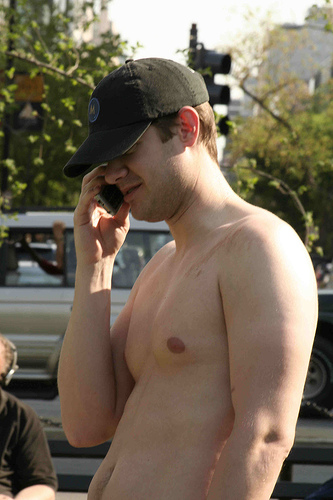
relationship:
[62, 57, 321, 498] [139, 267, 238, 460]
man has torso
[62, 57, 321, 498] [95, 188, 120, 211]
man holding cell phone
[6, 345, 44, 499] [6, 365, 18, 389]
man wearing headphones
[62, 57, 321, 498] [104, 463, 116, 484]
man has belly button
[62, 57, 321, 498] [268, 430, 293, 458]
man has elbow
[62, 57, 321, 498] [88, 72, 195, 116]
man wearing cap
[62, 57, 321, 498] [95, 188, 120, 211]
man talking on cell phone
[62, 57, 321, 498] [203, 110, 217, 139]
man has hair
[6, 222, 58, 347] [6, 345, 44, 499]
car behind man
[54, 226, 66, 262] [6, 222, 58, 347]
arm hanging out of car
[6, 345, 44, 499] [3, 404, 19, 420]
man wearing shirt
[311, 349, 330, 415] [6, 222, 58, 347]
tire of car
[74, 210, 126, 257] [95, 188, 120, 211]
hand holding cell phone